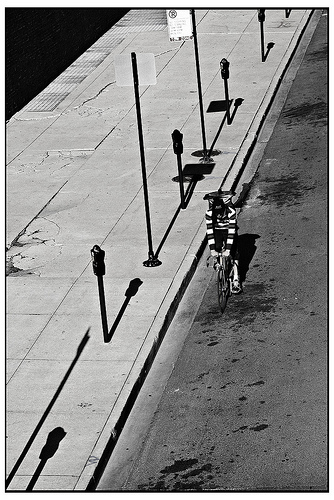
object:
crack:
[21, 110, 55, 115]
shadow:
[109, 275, 143, 338]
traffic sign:
[112, 44, 163, 269]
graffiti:
[84, 449, 100, 467]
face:
[214, 205, 225, 220]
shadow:
[27, 422, 67, 490]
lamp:
[114, 49, 157, 90]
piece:
[25, 115, 91, 180]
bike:
[204, 244, 235, 312]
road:
[94, 8, 327, 493]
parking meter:
[88, 243, 110, 344]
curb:
[86, 10, 317, 489]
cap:
[201, 187, 235, 202]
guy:
[202, 186, 245, 296]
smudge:
[230, 181, 252, 210]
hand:
[208, 249, 220, 259]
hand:
[219, 248, 231, 259]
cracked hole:
[4, 213, 64, 279]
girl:
[202, 188, 242, 296]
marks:
[280, 93, 327, 129]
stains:
[135, 453, 222, 493]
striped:
[207, 235, 216, 250]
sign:
[166, 8, 193, 42]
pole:
[190, 9, 208, 156]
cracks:
[34, 149, 50, 172]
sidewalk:
[6, 8, 315, 499]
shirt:
[204, 207, 238, 258]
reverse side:
[114, 51, 156, 89]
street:
[89, 7, 330, 496]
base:
[142, 252, 163, 269]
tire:
[216, 268, 228, 312]